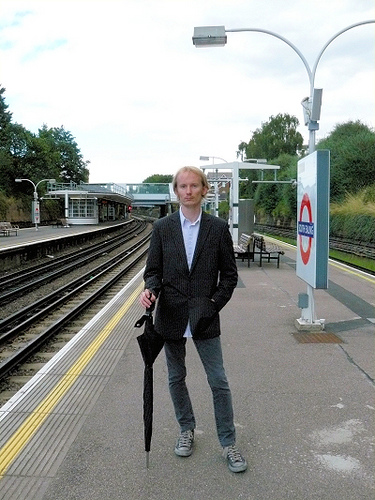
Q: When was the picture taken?
A: During the day.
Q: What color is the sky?
A: Blue.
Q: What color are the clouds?
A: White.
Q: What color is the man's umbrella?
A: Black.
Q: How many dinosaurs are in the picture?
A: Zero.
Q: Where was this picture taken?
A: At the train station.